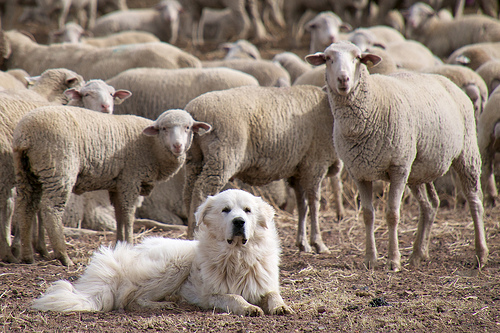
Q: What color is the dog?
A: White.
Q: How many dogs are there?
A: One.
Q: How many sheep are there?
A: More than five.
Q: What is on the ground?
A: Dirt.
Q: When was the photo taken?
A: Daytime.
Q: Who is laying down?
A: The dog.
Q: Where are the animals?
A: In a field.